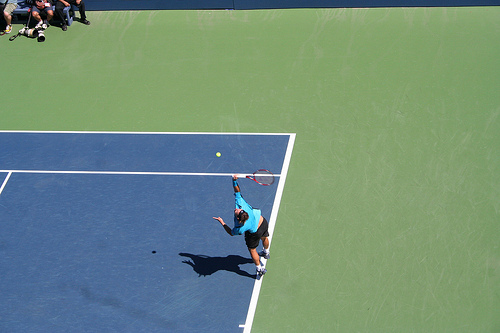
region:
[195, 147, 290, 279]
A person playing tennis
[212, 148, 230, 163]
A tennis ball in the air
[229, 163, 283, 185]
A person holding a racket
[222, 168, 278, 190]
A person holding a tennis racket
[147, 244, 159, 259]
The shadow of a tennis ball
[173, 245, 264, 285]
The shadow of a person playing tennis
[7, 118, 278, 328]
A blue tennis court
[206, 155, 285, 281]
A person swinging a racket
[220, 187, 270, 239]
A person wearing a blue shirt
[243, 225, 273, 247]
A person wearing black shorts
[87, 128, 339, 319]
the man is playing tennis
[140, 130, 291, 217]
tennis ball is in the air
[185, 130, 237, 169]
the ball is lime green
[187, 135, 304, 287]
the man is swinging the racket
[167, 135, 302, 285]
the player is in motion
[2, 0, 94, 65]
people sitting on the court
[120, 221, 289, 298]
shadow of the player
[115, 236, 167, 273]
shadow of the ball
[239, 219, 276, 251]
the man is wearing shorts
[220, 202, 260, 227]
the man has brown hair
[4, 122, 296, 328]
blue tennis court with white lines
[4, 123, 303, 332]
white lines on tennis court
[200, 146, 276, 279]
tennis player swinging at tennis ball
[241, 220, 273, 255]
black shorts of tennis player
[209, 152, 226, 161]
tennis ball player is swinging at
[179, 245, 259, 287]
shadow of tennis player on blue court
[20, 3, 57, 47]
person photographing tennis match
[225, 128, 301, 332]
white baseline of tennis court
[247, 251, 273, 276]
tennis shoes of player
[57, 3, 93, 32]
black socks of perso beside tennis court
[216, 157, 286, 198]
tennis racket is red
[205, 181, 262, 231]
man's shirt is blue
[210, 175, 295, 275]
man is leaning backwards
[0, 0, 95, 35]
people watching the player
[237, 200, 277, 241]
man's shirt has rose up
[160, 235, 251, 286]
shadow of man on court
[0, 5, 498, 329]
tennis court is green blue and white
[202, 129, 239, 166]
tennis ball in the air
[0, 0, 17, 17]
man's shorts are brown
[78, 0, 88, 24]
man's pants are black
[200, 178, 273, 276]
man playing tennis on court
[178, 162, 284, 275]
young man playing tennis on court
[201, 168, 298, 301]
young man playing tennis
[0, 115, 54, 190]
blue white and green tennis court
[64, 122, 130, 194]
blue white and green tennis court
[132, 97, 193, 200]
blue white and green tennis court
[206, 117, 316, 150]
blue white and green tennis court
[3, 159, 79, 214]
blue white and green tennis court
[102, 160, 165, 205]
blue white and green tennis court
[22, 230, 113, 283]
blue white and green tennis court